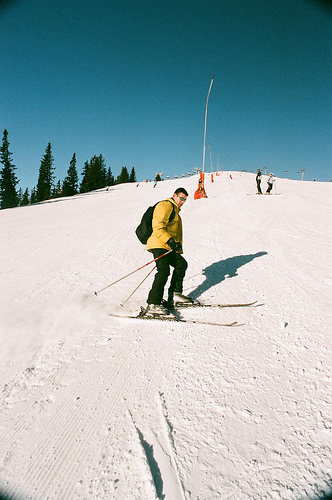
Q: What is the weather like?
A: It is cloudless.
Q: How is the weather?
A: It is cloudless.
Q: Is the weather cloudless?
A: Yes, it is cloudless.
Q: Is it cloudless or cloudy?
A: It is cloudless.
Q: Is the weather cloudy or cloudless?
A: It is cloudless.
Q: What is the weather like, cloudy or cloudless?
A: It is cloudless.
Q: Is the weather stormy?
A: No, it is cloudless.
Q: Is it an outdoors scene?
A: Yes, it is outdoors.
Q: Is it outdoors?
A: Yes, it is outdoors.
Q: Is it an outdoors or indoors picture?
A: It is outdoors.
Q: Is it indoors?
A: No, it is outdoors.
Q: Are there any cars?
A: No, there are no cars.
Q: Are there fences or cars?
A: No, there are no cars or fences.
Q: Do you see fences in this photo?
A: No, there are no fences.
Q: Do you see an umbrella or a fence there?
A: No, there are no fences or umbrellas.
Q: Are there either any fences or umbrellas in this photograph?
A: No, there are no fences or umbrellas.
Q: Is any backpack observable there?
A: Yes, there is a backpack.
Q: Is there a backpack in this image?
A: Yes, there is a backpack.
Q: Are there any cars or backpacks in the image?
A: Yes, there is a backpack.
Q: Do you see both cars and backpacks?
A: No, there is a backpack but no cars.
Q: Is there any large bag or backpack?
A: Yes, there is a large backpack.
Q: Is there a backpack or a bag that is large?
A: Yes, the backpack is large.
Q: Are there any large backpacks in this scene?
A: Yes, there is a large backpack.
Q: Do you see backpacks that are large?
A: Yes, there is a backpack that is large.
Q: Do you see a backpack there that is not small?
A: Yes, there is a large backpack.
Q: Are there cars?
A: No, there are no cars.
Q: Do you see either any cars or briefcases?
A: No, there are no cars or briefcases.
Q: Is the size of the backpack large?
A: Yes, the backpack is large.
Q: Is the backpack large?
A: Yes, the backpack is large.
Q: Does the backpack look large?
A: Yes, the backpack is large.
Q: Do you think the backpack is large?
A: Yes, the backpack is large.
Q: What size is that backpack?
A: The backpack is large.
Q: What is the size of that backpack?
A: The backpack is large.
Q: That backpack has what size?
A: The backpack is large.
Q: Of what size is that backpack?
A: The backpack is large.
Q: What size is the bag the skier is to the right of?
A: The backpack is large.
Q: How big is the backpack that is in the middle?
A: The backpack is large.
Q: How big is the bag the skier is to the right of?
A: The backpack is large.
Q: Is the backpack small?
A: No, the backpack is large.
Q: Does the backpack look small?
A: No, the backpack is large.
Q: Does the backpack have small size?
A: No, the backpack is large.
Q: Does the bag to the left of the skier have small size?
A: No, the backpack is large.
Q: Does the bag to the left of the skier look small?
A: No, the backpack is large.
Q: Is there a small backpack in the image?
A: No, there is a backpack but it is large.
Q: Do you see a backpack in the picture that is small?
A: No, there is a backpack but it is large.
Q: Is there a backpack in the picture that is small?
A: No, there is a backpack but it is large.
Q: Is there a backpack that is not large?
A: No, there is a backpack but it is large.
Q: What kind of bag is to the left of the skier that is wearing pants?
A: The bag is a backpack.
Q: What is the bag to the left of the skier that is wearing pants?
A: The bag is a backpack.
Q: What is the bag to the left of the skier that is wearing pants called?
A: The bag is a backpack.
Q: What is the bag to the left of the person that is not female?
A: The bag is a backpack.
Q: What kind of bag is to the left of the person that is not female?
A: The bag is a backpack.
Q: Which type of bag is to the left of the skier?
A: The bag is a backpack.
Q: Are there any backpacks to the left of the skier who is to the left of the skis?
A: Yes, there is a backpack to the left of the skier.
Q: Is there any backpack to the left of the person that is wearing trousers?
A: Yes, there is a backpack to the left of the skier.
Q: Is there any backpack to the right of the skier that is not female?
A: No, the backpack is to the left of the skier.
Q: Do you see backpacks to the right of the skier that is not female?
A: No, the backpack is to the left of the skier.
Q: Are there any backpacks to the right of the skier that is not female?
A: No, the backpack is to the left of the skier.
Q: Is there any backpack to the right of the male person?
A: No, the backpack is to the left of the skier.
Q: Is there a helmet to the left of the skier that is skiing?
A: No, there is a backpack to the left of the skier.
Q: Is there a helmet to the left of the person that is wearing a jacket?
A: No, there is a backpack to the left of the skier.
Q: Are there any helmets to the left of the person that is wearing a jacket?
A: No, there is a backpack to the left of the skier.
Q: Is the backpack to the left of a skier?
A: Yes, the backpack is to the left of a skier.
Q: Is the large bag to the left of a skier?
A: Yes, the backpack is to the left of a skier.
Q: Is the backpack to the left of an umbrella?
A: No, the backpack is to the left of a skier.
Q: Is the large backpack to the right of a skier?
A: No, the backpack is to the left of a skier.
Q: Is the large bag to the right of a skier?
A: No, the backpack is to the left of a skier.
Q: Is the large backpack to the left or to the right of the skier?
A: The backpack is to the left of the skier.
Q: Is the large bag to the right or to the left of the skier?
A: The backpack is to the left of the skier.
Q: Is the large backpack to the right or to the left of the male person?
A: The backpack is to the left of the skier.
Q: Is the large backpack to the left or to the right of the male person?
A: The backpack is to the left of the skier.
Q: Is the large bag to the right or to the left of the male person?
A: The backpack is to the left of the skier.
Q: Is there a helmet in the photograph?
A: No, there are no helmets.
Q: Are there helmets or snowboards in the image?
A: No, there are no helmets or snowboards.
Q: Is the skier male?
A: Yes, the skier is male.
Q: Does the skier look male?
A: Yes, the skier is male.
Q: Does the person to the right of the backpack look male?
A: Yes, the skier is male.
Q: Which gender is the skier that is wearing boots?
A: The skier is male.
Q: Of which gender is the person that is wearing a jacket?
A: The skier is male.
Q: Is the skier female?
A: No, the skier is male.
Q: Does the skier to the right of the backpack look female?
A: No, the skier is male.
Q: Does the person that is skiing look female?
A: No, the skier is male.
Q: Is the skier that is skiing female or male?
A: The skier is male.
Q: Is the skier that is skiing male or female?
A: The skier is male.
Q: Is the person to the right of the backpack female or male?
A: The skier is male.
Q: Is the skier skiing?
A: Yes, the skier is skiing.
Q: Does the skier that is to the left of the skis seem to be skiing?
A: Yes, the skier is skiing.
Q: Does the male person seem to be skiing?
A: Yes, the skier is skiing.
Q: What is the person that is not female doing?
A: The skier is skiing.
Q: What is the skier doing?
A: The skier is skiing.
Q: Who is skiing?
A: The skier is skiing.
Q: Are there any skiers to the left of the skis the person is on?
A: Yes, there is a skier to the left of the skis.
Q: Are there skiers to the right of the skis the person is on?
A: No, the skier is to the left of the skis.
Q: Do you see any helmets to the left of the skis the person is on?
A: No, there is a skier to the left of the skis.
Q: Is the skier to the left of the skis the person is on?
A: Yes, the skier is to the left of the skis.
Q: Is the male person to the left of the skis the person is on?
A: Yes, the skier is to the left of the skis.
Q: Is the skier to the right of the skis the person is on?
A: No, the skier is to the left of the skis.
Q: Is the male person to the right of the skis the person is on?
A: No, the skier is to the left of the skis.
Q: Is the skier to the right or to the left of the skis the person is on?
A: The skier is to the left of the skis.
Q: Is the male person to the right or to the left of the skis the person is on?
A: The skier is to the left of the skis.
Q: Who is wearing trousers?
A: The skier is wearing trousers.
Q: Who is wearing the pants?
A: The skier is wearing trousers.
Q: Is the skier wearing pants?
A: Yes, the skier is wearing pants.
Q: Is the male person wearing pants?
A: Yes, the skier is wearing pants.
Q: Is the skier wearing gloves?
A: No, the skier is wearing pants.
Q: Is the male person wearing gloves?
A: No, the skier is wearing pants.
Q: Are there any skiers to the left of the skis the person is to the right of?
A: Yes, there is a skier to the left of the skis.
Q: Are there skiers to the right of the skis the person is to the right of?
A: No, the skier is to the left of the skis.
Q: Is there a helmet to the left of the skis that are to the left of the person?
A: No, there is a skier to the left of the skis.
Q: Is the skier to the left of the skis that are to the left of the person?
A: Yes, the skier is to the left of the skis.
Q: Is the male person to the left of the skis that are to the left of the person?
A: Yes, the skier is to the left of the skis.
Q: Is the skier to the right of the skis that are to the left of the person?
A: No, the skier is to the left of the skis.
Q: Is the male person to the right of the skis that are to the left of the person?
A: No, the skier is to the left of the skis.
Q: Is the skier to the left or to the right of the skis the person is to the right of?
A: The skier is to the left of the skis.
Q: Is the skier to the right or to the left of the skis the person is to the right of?
A: The skier is to the left of the skis.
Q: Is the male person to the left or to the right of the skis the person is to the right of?
A: The skier is to the left of the skis.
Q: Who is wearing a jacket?
A: The skier is wearing a jacket.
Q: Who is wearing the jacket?
A: The skier is wearing a jacket.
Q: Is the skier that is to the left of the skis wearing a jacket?
A: Yes, the skier is wearing a jacket.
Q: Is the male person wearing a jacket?
A: Yes, the skier is wearing a jacket.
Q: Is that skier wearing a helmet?
A: No, the skier is wearing a jacket.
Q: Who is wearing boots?
A: The skier is wearing boots.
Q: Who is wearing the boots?
A: The skier is wearing boots.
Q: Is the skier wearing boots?
A: Yes, the skier is wearing boots.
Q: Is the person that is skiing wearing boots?
A: Yes, the skier is wearing boots.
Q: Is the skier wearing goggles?
A: No, the skier is wearing boots.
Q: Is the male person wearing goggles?
A: No, the skier is wearing boots.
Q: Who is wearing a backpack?
A: The skier is wearing a backpack.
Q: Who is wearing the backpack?
A: The skier is wearing a backpack.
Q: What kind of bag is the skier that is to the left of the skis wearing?
A: The skier is wearing a backpack.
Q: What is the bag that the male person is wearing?
A: The bag is a backpack.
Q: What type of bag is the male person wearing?
A: The skier is wearing a backpack.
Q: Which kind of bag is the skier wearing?
A: The skier is wearing a backpack.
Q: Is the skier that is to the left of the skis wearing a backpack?
A: Yes, the skier is wearing a backpack.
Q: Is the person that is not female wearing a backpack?
A: Yes, the skier is wearing a backpack.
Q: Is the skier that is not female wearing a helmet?
A: No, the skier is wearing a backpack.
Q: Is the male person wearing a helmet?
A: No, the skier is wearing a backpack.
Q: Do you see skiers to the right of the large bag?
A: Yes, there is a skier to the right of the backpack.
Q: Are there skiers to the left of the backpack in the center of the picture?
A: No, the skier is to the right of the backpack.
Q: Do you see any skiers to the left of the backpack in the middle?
A: No, the skier is to the right of the backpack.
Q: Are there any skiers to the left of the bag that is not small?
A: No, the skier is to the right of the backpack.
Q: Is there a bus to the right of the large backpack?
A: No, there is a skier to the right of the backpack.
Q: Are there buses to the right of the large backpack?
A: No, there is a skier to the right of the backpack.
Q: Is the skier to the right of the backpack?
A: Yes, the skier is to the right of the backpack.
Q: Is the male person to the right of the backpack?
A: Yes, the skier is to the right of the backpack.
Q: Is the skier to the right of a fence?
A: No, the skier is to the right of the backpack.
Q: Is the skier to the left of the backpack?
A: No, the skier is to the right of the backpack.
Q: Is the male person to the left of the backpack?
A: No, the skier is to the right of the backpack.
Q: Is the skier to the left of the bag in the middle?
A: No, the skier is to the right of the backpack.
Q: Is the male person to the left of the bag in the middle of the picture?
A: No, the skier is to the right of the backpack.